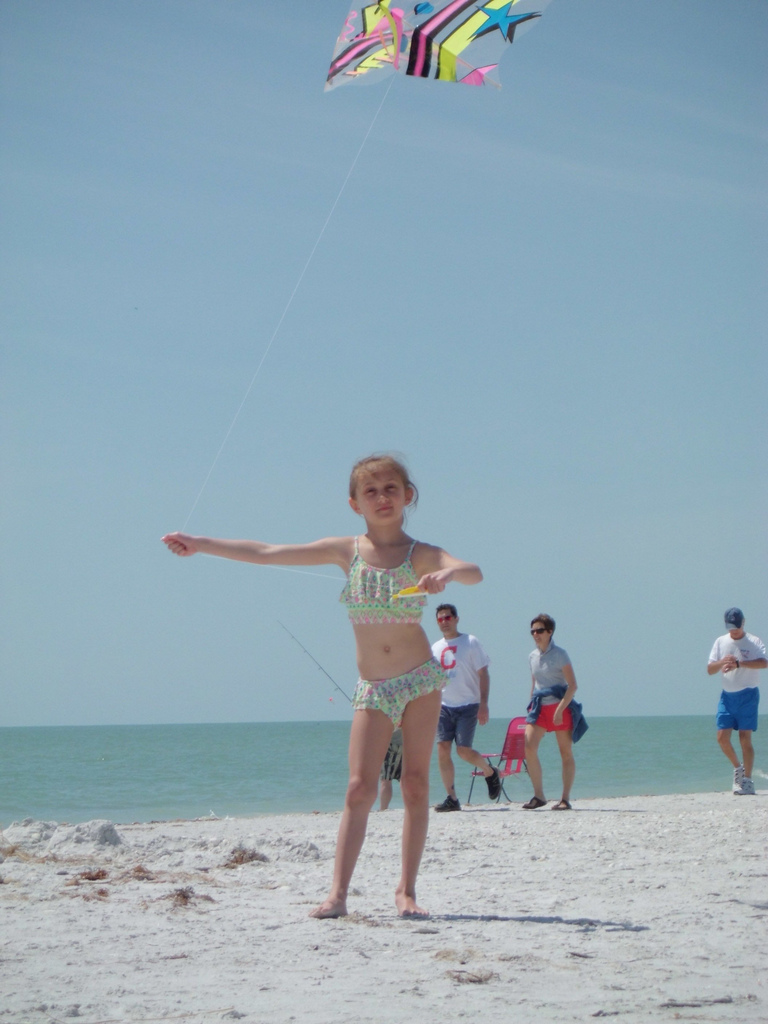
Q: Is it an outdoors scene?
A: Yes, it is outdoors.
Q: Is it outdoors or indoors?
A: It is outdoors.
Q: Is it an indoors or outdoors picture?
A: It is outdoors.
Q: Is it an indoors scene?
A: No, it is outdoors.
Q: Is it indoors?
A: No, it is outdoors.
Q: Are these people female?
A: No, they are both male and female.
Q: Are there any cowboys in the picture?
A: No, there are no cowboys.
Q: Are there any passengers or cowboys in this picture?
A: No, there are no cowboys or passengers.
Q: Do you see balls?
A: No, there are no balls.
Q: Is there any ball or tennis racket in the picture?
A: No, there are no balls or rackets.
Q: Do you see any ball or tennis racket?
A: No, there are no balls or rackets.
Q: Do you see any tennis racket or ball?
A: No, there are no balls or rackets.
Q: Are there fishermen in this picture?
A: No, there are no fishermen.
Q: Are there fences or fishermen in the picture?
A: No, there are no fishermen or fences.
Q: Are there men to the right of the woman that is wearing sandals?
A: Yes, there is a man to the right of the woman.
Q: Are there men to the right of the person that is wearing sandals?
A: Yes, there is a man to the right of the woman.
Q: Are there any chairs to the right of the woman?
A: No, there is a man to the right of the woman.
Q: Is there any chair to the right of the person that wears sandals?
A: No, there is a man to the right of the woman.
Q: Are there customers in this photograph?
A: No, there are no customers.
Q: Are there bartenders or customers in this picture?
A: No, there are no customers or bartenders.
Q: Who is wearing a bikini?
A: The girl is wearing a bikini.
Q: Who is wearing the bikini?
A: The girl is wearing a bikini.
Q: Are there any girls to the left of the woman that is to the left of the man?
A: Yes, there is a girl to the left of the woman.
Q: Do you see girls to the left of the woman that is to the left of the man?
A: Yes, there is a girl to the left of the woman.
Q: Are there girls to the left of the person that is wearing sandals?
A: Yes, there is a girl to the left of the woman.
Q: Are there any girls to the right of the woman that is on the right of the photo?
A: No, the girl is to the left of the woman.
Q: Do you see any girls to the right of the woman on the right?
A: No, the girl is to the left of the woman.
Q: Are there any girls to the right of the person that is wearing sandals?
A: No, the girl is to the left of the woman.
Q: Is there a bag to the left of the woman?
A: No, there is a girl to the left of the woman.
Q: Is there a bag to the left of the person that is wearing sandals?
A: No, there is a girl to the left of the woman.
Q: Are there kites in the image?
A: Yes, there is a kite.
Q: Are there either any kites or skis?
A: Yes, there is a kite.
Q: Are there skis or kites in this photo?
A: Yes, there is a kite.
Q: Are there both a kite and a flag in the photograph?
A: No, there is a kite but no flags.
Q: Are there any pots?
A: No, there are no pots.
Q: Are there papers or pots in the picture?
A: No, there are no pots or papers.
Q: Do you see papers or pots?
A: No, there are no pots or papers.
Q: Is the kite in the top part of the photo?
A: Yes, the kite is in the top of the image.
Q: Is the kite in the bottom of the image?
A: No, the kite is in the top of the image.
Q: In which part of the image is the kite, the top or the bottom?
A: The kite is in the top of the image.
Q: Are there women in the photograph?
A: Yes, there is a woman.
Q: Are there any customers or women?
A: Yes, there is a woman.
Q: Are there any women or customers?
A: Yes, there is a woman.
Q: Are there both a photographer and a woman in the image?
A: No, there is a woman but no photographers.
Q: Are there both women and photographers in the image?
A: No, there is a woman but no photographers.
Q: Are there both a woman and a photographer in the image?
A: No, there is a woman but no photographers.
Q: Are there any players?
A: No, there are no players.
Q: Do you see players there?
A: No, there are no players.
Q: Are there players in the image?
A: No, there are no players.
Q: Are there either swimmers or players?
A: No, there are no players or swimmers.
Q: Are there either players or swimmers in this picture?
A: No, there are no players or swimmers.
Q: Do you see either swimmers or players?
A: No, there are no players or swimmers.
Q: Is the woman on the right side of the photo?
A: Yes, the woman is on the right of the image.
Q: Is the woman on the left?
A: No, the woman is on the right of the image.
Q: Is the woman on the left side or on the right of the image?
A: The woman is on the right of the image.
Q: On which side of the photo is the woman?
A: The woman is on the right of the image.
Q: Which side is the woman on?
A: The woman is on the right of the image.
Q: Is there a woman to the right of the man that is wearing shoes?
A: Yes, there is a woman to the right of the man.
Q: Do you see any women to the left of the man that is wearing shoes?
A: No, the woman is to the right of the man.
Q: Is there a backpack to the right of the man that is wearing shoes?
A: No, there is a woman to the right of the man.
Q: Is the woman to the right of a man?
A: Yes, the woman is to the right of a man.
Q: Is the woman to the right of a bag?
A: No, the woman is to the right of a man.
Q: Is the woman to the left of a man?
A: No, the woman is to the right of a man.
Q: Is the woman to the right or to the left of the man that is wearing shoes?
A: The woman is to the right of the man.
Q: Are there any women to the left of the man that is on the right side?
A: Yes, there is a woman to the left of the man.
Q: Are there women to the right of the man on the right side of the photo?
A: No, the woman is to the left of the man.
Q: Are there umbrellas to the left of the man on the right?
A: No, there is a woman to the left of the man.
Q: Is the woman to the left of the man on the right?
A: Yes, the woman is to the left of the man.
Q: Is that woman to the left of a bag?
A: No, the woman is to the left of the man.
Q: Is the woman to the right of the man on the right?
A: No, the woman is to the left of the man.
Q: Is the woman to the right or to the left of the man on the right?
A: The woman is to the left of the man.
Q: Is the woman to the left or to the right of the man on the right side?
A: The woman is to the left of the man.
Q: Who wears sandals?
A: The woman wears sandals.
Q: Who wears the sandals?
A: The woman wears sandals.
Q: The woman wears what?
A: The woman wears sandals.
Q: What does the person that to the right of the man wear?
A: The woman wears sandals.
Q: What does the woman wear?
A: The woman wears sandals.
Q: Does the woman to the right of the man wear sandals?
A: Yes, the woman wears sandals.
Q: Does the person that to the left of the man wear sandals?
A: Yes, the woman wears sandals.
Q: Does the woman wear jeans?
A: No, the woman wears sandals.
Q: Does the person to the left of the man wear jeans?
A: No, the woman wears sandals.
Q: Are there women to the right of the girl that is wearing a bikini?
A: Yes, there is a woman to the right of the girl.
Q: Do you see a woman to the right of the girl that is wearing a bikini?
A: Yes, there is a woman to the right of the girl.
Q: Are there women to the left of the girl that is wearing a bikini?
A: No, the woman is to the right of the girl.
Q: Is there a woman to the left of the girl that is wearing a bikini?
A: No, the woman is to the right of the girl.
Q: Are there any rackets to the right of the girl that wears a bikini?
A: No, there is a woman to the right of the girl.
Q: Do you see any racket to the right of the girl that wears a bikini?
A: No, there is a woman to the right of the girl.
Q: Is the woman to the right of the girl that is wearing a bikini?
A: Yes, the woman is to the right of the girl.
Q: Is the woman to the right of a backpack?
A: No, the woman is to the right of the girl.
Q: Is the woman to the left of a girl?
A: No, the woman is to the right of a girl.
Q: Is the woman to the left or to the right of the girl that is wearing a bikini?
A: The woman is to the right of the girl.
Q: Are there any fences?
A: No, there are no fences.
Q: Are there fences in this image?
A: No, there are no fences.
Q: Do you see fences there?
A: No, there are no fences.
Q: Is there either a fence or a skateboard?
A: No, there are no fences or skateboards.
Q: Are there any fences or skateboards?
A: No, there are no fences or skateboards.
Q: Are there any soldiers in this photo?
A: No, there are no soldiers.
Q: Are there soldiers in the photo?
A: No, there are no soldiers.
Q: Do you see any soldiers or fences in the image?
A: No, there are no soldiers or fences.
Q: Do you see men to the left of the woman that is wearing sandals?
A: Yes, there is a man to the left of the woman.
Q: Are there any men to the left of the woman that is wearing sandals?
A: Yes, there is a man to the left of the woman.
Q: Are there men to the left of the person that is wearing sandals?
A: Yes, there is a man to the left of the woman.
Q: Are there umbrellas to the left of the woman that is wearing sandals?
A: No, there is a man to the left of the woman.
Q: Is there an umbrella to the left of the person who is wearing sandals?
A: No, there is a man to the left of the woman.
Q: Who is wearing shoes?
A: The man is wearing shoes.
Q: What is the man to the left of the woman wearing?
A: The man is wearing shoes.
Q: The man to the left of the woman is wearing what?
A: The man is wearing shoes.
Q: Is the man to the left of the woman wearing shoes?
A: Yes, the man is wearing shoes.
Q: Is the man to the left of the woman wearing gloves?
A: No, the man is wearing shoes.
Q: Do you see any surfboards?
A: No, there are no surfboards.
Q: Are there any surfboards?
A: No, there are no surfboards.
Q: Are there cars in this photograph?
A: No, there are no cars.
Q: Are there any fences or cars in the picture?
A: No, there are no cars or fences.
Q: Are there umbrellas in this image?
A: No, there are no umbrellas.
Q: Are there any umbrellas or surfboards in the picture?
A: No, there are no umbrellas or surfboards.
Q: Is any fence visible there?
A: No, there are no fences.